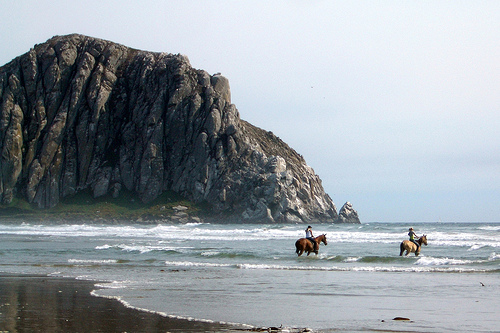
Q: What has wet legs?
A: Horses.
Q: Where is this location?
A: Beach.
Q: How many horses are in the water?
A: Two.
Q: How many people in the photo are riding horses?
A: Two.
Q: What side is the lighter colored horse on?
A: Right.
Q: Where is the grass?
A: Near the rock hill.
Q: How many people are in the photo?
A: Two.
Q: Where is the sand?
A: Bottom left corner.